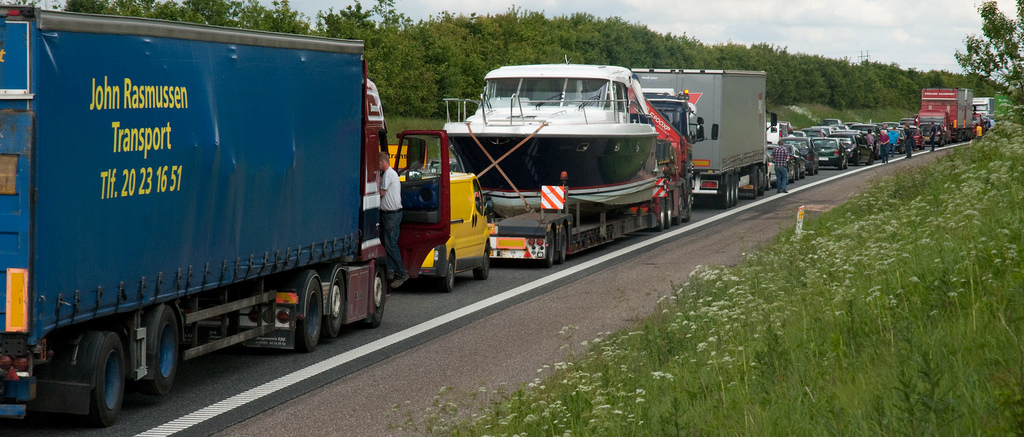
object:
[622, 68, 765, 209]
truck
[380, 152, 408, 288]
person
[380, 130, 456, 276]
door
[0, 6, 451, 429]
truck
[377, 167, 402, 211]
shirt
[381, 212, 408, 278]
pants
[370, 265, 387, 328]
front tire